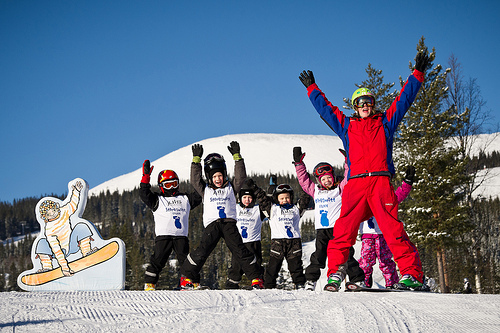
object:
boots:
[393, 274, 431, 290]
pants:
[180, 219, 263, 280]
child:
[137, 158, 205, 291]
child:
[224, 174, 277, 288]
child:
[291, 146, 367, 292]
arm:
[295, 69, 348, 134]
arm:
[292, 146, 314, 196]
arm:
[228, 140, 248, 192]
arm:
[191, 144, 206, 198]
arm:
[395, 165, 416, 203]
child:
[262, 174, 311, 290]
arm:
[297, 191, 311, 214]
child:
[178, 140, 266, 290]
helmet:
[351, 87, 376, 107]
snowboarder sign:
[17, 177, 125, 291]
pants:
[144, 236, 200, 284]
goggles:
[354, 97, 375, 108]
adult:
[297, 48, 429, 289]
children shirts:
[150, 187, 315, 240]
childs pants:
[143, 220, 400, 286]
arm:
[139, 159, 157, 208]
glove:
[227, 140, 241, 156]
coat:
[305, 69, 428, 181]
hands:
[414, 52, 431, 72]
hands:
[293, 147, 306, 163]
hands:
[227, 141, 240, 156]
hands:
[269, 175, 277, 184]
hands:
[142, 159, 154, 178]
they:
[299, 49, 433, 293]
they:
[246, 179, 309, 290]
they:
[180, 140, 264, 290]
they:
[139, 159, 208, 291]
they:
[224, 173, 278, 291]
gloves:
[416, 52, 430, 73]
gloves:
[297, 69, 316, 87]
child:
[357, 165, 417, 290]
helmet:
[158, 169, 180, 194]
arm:
[386, 47, 434, 131]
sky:
[0, 0, 500, 177]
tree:
[385, 36, 489, 264]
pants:
[326, 173, 425, 283]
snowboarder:
[345, 282, 432, 292]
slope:
[0, 289, 500, 333]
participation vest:
[153, 183, 384, 244]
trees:
[0, 148, 500, 295]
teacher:
[299, 49, 431, 289]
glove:
[140, 159, 154, 184]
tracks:
[0, 290, 500, 333]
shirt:
[200, 180, 238, 227]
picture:
[17, 177, 124, 291]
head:
[353, 92, 375, 118]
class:
[137, 46, 430, 292]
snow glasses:
[159, 179, 179, 190]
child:
[298, 48, 432, 292]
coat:
[294, 162, 349, 231]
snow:
[0, 291, 497, 333]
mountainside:
[0, 244, 491, 329]